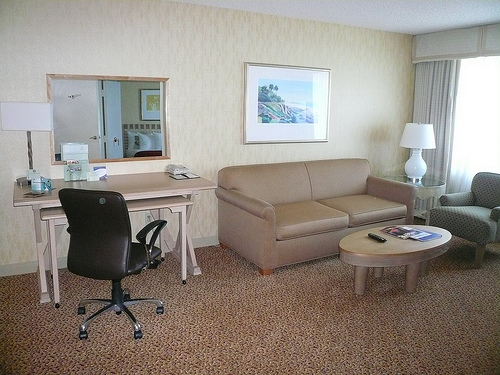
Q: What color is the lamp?
A: White.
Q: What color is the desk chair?
A: Black.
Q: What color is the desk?
A: Brown.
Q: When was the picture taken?
A: Daytime.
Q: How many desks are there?
A: One.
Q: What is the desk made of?
A: Wood.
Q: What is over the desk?
A: The mirror.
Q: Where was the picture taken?
A: In a hotel.